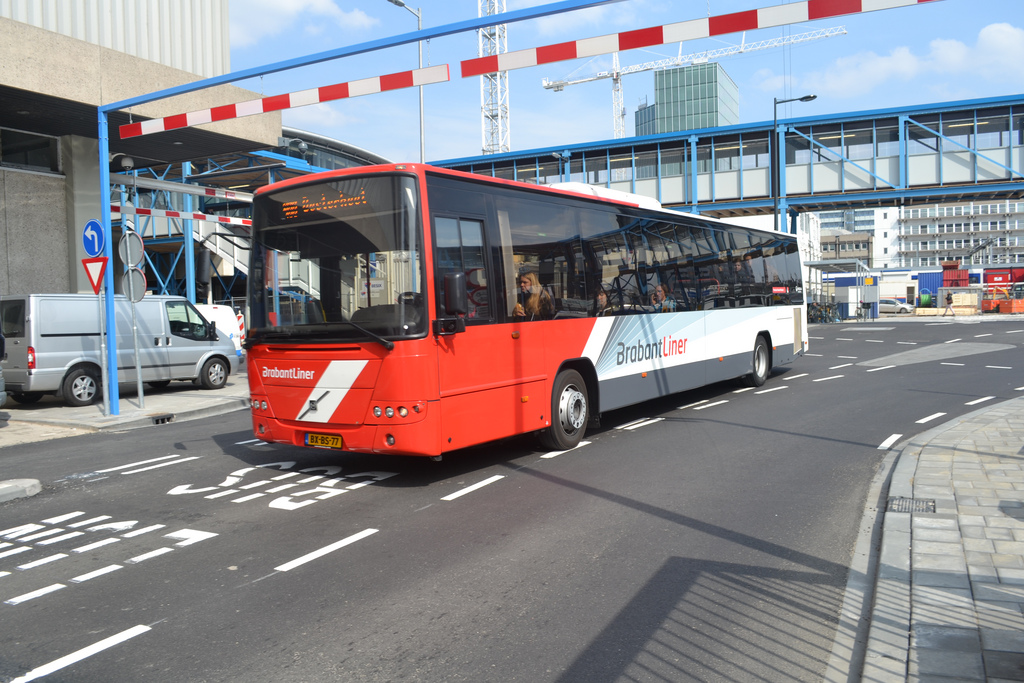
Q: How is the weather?
A: It is cloudy.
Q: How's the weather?
A: It is cloudy.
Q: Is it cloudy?
A: Yes, it is cloudy.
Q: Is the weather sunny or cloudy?
A: It is cloudy.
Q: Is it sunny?
A: No, it is cloudy.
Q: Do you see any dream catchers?
A: No, there are no dream catchers.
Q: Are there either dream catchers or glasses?
A: No, there are no dream catchers or glasses.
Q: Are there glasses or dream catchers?
A: No, there are no dream catchers or glasses.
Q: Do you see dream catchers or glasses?
A: No, there are no dream catchers or glasses.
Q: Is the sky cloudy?
A: Yes, the sky is cloudy.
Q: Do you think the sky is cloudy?
A: Yes, the sky is cloudy.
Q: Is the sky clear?
A: No, the sky is cloudy.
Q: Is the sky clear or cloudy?
A: The sky is cloudy.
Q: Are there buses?
A: Yes, there is a bus.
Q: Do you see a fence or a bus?
A: Yes, there is a bus.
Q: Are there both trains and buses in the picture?
A: No, there is a bus but no trains.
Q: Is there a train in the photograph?
A: No, there are no trains.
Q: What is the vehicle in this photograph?
A: The vehicle is a bus.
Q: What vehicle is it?
A: The vehicle is a bus.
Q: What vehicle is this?
A: This is a bus.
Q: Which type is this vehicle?
A: This is a bus.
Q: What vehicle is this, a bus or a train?
A: This is a bus.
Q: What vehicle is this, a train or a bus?
A: This is a bus.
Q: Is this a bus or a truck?
A: This is a bus.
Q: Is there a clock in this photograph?
A: No, there are no clocks.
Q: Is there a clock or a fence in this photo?
A: No, there are no clocks or fences.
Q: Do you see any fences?
A: No, there are no fences.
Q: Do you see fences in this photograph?
A: No, there are no fences.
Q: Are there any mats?
A: No, there are no mats.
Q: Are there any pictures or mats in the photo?
A: No, there are no mats or pictures.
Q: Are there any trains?
A: No, there are no trains.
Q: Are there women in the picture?
A: Yes, there is a woman.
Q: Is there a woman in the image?
A: Yes, there is a woman.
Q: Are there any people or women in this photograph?
A: Yes, there is a woman.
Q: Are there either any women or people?
A: Yes, there is a woman.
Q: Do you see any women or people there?
A: Yes, there is a woman.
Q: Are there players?
A: No, there are no players.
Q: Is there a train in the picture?
A: No, there are no trains.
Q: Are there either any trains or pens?
A: No, there are no trains or pens.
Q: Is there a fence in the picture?
A: No, there are no fences.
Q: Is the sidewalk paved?
A: Yes, the sidewalk is paved.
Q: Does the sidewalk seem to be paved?
A: Yes, the sidewalk is paved.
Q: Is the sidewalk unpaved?
A: No, the sidewalk is paved.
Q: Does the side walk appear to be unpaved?
A: No, the side walk is paved.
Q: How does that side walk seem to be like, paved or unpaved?
A: The side walk is paved.